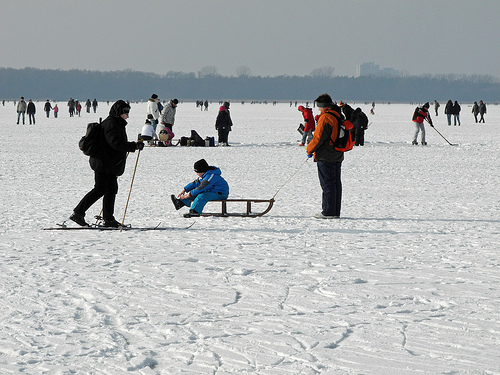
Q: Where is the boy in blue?
A: On a sled.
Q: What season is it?
A: Winter.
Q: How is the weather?
A: Cold.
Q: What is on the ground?
A: Snow.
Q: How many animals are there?
A: None.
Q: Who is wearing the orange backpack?
A: The man in the orange coat.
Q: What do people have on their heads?
A: Hats.